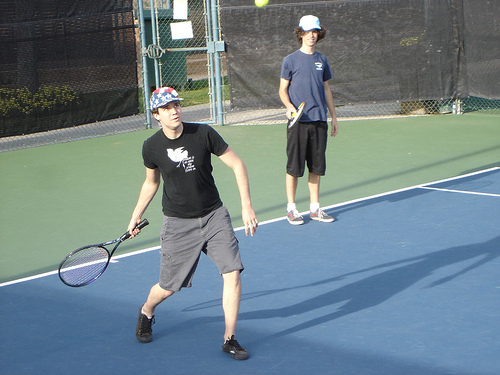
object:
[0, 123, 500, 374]
ground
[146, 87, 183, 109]
cap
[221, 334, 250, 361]
sneakers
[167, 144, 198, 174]
print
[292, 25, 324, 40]
hair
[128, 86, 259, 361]
boy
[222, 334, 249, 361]
shoe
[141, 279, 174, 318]
bare leg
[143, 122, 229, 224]
tshirt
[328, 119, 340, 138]
hand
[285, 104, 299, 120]
hand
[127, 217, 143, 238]
hand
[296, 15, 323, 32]
baseball cap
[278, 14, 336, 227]
boy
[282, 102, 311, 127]
racquet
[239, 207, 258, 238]
hand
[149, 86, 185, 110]
hat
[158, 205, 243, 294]
shorts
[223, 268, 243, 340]
leg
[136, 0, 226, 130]
fence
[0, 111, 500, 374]
court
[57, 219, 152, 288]
black racket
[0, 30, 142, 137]
fence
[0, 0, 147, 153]
cover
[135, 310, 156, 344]
shoe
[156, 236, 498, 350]
shadow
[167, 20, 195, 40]
paper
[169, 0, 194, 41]
signs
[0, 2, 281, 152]
court gate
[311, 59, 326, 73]
print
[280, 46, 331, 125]
shirt